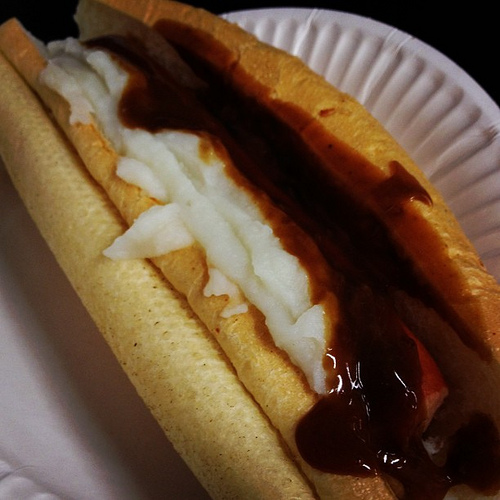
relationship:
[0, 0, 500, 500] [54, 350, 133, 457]
bun casting shadow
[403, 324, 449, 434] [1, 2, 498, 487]
hot dog on bun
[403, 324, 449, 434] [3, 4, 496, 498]
hot dog on hotdog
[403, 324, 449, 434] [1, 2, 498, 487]
hot dog in bun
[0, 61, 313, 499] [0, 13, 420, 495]
spots on bun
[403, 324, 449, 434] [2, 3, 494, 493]
hot dog on hot dog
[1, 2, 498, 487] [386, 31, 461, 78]
bun on plate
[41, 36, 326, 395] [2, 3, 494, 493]
onions on hot dog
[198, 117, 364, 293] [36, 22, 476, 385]
potatoes on hotdog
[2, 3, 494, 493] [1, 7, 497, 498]
hot dog on plate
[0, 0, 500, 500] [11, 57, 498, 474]
bun on bun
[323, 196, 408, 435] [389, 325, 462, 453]
gravy on brat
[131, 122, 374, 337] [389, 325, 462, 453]
potatoes on brat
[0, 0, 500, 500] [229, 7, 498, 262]
bun on plate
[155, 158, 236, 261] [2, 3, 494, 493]
onions on hot dog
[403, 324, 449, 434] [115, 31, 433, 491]
hot dog beneath sauce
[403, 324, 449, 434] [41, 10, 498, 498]
hot dog under sauce